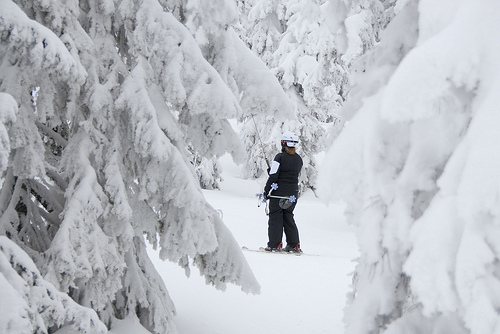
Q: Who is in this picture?
A: A skier.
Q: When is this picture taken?
A: Winter.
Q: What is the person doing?
A: Skiing.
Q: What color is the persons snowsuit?
A: Black.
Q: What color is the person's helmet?
A: White.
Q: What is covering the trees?
A: Snow.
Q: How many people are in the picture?
A: One.